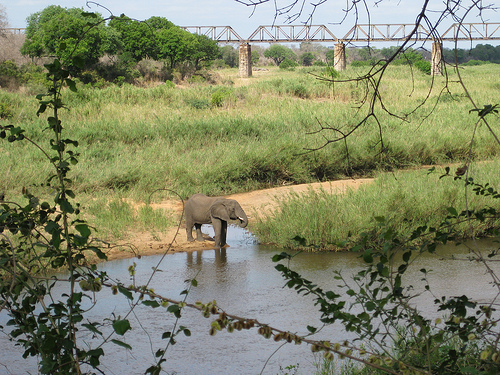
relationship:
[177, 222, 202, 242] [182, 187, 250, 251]
leg of elephant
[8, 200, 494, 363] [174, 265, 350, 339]
water has ripples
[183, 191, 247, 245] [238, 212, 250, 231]
elephant has trunk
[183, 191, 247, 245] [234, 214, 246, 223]
elephant has tusk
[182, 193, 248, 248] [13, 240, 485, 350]
elephant near water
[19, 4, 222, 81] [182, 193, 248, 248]
tree around elephant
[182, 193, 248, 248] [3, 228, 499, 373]
elephant at water